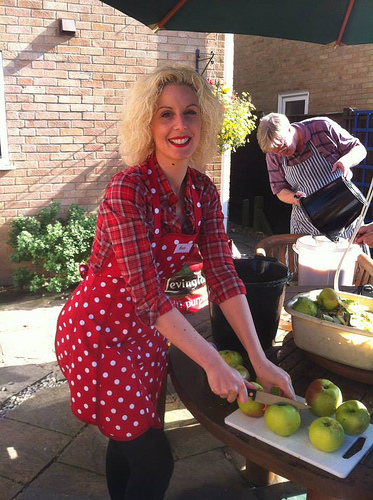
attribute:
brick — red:
[1, 1, 233, 289]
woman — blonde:
[56, 61, 296, 499]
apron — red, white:
[55, 165, 202, 440]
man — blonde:
[256, 112, 366, 235]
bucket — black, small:
[299, 177, 367, 242]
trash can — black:
[211, 256, 288, 347]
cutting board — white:
[223, 393, 372, 479]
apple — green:
[309, 416, 345, 453]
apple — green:
[306, 377, 342, 417]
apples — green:
[237, 378, 369, 451]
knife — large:
[245, 387, 314, 411]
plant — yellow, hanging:
[206, 77, 257, 153]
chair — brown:
[255, 234, 372, 283]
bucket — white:
[292, 234, 360, 285]